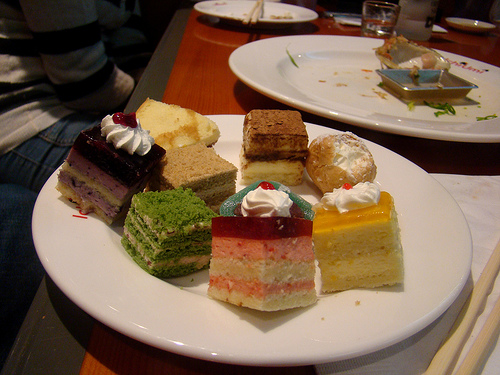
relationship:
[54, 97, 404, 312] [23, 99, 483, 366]
cakes in plate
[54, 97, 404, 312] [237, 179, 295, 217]
cakes in whip cream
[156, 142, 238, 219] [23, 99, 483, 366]
petit four in plate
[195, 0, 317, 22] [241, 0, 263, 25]
empty plate in chopsticks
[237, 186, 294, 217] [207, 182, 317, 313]
cream in cake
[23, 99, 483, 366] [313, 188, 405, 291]
plate in cake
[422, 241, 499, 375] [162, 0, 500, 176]
chopstick on ground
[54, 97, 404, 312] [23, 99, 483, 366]
cakes on plate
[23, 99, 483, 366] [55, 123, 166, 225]
plate filled with dessert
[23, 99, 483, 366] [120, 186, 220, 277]
plate filled with dessert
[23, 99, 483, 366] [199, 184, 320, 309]
plate filled with petit four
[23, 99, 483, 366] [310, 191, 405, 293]
plate filled with dessert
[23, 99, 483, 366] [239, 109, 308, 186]
plate filled with dessert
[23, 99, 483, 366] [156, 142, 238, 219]
plate filled with petit four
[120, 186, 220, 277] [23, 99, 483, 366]
dessert on plate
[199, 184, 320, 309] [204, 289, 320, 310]
petit four with layer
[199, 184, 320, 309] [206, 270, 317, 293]
petit four with layer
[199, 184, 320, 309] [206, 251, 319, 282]
petit four with layer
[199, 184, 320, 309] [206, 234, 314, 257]
petit four with layer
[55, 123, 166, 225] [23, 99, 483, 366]
dessert on plate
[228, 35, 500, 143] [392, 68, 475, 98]
empty plate with cup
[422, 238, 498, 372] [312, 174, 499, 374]
chopstick on napkin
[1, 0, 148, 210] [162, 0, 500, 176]
person sitting at ground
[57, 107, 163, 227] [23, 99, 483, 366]
dessert on plate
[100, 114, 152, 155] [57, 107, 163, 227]
cream on top of dessert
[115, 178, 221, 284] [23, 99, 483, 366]
dessert on plate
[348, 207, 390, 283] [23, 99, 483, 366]
dessert on plate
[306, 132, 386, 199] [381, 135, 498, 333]
dessert on top of plate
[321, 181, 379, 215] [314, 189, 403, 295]
whip cream on dessert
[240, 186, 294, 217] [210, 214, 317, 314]
cream on dessert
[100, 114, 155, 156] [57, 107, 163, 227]
cream on dessert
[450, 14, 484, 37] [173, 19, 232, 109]
saucer on table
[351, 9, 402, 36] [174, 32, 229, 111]
glass on table